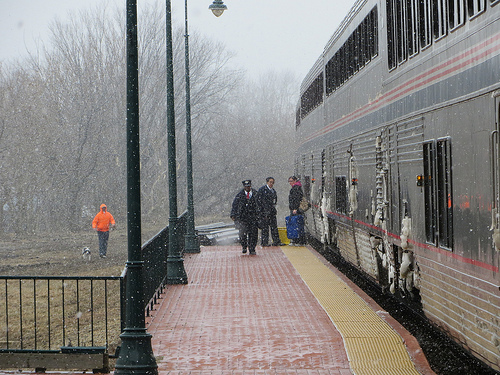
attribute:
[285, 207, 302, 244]
suitcase — blue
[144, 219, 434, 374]
ground — red, wet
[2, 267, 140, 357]
fence — metal, dark, green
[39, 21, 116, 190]
bare trees — tall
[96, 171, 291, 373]
platform — red, brick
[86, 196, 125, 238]
coat — bright, orange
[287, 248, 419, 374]
stripe — yellow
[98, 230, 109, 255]
pants — blue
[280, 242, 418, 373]
stripe — yellow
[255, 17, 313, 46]
grey sky — wintery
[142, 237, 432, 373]
pavement — red, brick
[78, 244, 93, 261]
dog — black, white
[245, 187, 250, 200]
tie — red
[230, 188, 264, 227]
coat — dark